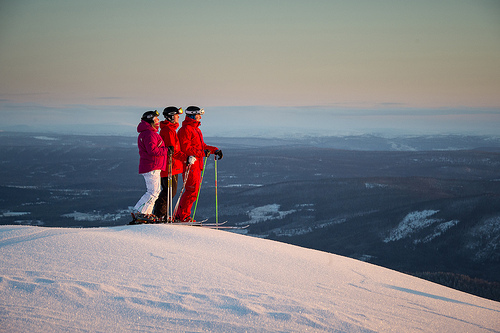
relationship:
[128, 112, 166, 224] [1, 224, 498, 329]
skier are standing on mountain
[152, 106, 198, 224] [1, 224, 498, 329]
middle are standing on mountain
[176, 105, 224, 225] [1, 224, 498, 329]
skier are standing on mountain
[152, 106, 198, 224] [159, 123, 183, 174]
middle wearing red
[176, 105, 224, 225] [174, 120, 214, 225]
skier wearing red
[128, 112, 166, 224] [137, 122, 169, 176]
skier wearing coat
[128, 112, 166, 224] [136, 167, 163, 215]
woman wearing pants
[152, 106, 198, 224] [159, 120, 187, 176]
middle wearing coat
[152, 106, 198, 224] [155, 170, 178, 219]
middle wearing pants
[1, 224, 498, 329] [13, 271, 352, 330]
snow has tracks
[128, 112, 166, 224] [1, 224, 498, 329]
skier standing on mountain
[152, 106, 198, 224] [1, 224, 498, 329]
middle standing on mountain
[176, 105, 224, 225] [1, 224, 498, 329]
skier standing on mountain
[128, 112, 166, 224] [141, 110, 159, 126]
skier wearing helmet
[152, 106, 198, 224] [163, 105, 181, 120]
middle wearing helmet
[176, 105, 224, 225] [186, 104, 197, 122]
skier wearing helmet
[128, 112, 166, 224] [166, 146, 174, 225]
skier has ski poles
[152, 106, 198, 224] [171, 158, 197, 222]
middle has ski poles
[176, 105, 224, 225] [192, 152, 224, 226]
skier has ski poles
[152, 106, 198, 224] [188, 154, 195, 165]
middle has glove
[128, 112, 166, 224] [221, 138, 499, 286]
skier looking off distance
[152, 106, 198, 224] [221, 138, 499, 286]
middle looking off distance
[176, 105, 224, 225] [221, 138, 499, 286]
skier looking off distance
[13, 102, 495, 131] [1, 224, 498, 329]
clouds are over mountain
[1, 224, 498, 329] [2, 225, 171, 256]
snow has shadow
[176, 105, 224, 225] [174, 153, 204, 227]
skier wearing pants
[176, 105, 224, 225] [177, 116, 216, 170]
skier wearing coat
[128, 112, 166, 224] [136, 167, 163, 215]
skier wearing pants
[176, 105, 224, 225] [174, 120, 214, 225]
person in all red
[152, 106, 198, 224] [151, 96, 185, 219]
middle in middle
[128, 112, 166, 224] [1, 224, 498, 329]
skier in snow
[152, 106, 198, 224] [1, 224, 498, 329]
middle in snow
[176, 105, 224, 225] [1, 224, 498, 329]
skier in snow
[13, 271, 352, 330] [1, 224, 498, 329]
tracks are in snow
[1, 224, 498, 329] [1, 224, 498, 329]
snow on mountain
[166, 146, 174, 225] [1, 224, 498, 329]
ski poles are on mountain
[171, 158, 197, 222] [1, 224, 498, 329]
ski poles are on mountain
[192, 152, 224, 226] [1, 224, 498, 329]
ski poles are on mountain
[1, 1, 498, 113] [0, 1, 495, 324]
sky in background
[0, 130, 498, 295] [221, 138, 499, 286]
land in distance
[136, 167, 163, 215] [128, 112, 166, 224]
pants are on skier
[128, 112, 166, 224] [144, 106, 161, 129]
skier has head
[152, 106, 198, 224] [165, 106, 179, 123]
middle has head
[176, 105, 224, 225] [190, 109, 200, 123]
skier has head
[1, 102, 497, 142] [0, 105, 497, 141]
mountain in horizon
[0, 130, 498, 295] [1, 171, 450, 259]
land covered with snow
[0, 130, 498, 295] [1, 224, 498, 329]
land covered with snow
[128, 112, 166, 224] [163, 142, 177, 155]
skier has hand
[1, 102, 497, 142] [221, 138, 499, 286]
mountain in distance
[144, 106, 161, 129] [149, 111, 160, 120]
head has snow goggles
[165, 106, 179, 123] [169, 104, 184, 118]
head has snow goggles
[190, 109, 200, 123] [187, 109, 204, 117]
head has snow goggles